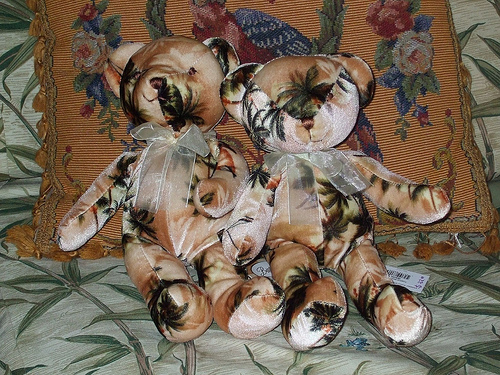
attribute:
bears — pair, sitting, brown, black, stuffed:
[56, 36, 449, 349]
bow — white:
[131, 123, 211, 221]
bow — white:
[259, 150, 366, 226]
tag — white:
[385, 262, 431, 297]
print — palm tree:
[227, 70, 332, 148]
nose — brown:
[296, 115, 325, 134]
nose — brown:
[147, 72, 171, 94]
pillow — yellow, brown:
[9, 1, 498, 262]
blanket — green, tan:
[1, 2, 488, 373]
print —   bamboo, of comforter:
[3, 261, 157, 373]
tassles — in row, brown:
[12, 1, 55, 247]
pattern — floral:
[358, 4, 464, 135]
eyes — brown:
[128, 65, 200, 82]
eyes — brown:
[261, 90, 340, 112]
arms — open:
[224, 155, 452, 264]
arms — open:
[59, 140, 253, 251]